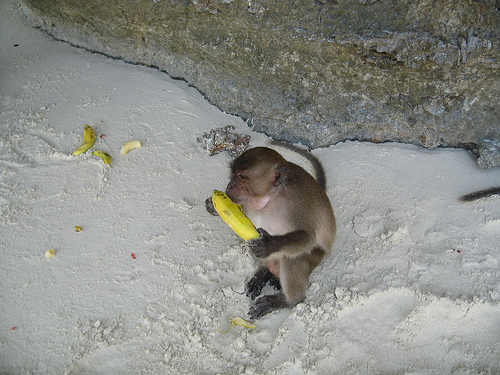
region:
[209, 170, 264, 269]
The monkey is holding a banana.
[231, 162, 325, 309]
A monkey sitting in the snow.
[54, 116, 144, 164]
Banana peel on the ground.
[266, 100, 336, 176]
The monkey has a long tail.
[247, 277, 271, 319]
Claws on the monkey.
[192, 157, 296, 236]
The monkey is eating a banana.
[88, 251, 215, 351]
Footprints on the snow.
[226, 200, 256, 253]
The banana is yellow.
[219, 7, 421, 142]
A big rock on side of monkey.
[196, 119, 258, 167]
A brown object on the snow.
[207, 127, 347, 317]
monkey holding banana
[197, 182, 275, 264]
a yellow banana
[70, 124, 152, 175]
a banana peel and a unpeeled banana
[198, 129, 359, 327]
monkey trying to eat banana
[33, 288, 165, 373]
a snow plain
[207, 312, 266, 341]
pieces of banana skin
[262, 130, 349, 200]
tail of a monkey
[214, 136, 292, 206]
head of a monkey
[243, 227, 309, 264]
arm of a monkey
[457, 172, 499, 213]
a monkey's tail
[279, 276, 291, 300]
part of a thigh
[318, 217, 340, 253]
part of a monkey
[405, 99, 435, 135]
oart of a wall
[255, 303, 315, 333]
aprt of a foot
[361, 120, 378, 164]
part of a rock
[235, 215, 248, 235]
part of a banana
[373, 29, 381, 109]
part of a rock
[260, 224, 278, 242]
part of a banana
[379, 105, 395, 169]
part of a stone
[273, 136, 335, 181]
The tail of the monkey.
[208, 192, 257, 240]
The banana in the monkey's hand.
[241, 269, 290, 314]
The feet of the monkey.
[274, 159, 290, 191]
The ear of the monkey.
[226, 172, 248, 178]
The eyes of the monkey.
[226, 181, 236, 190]
The nose of the monkey.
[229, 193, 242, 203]
The mouth of the monkey.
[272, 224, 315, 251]
The arm of the monkey.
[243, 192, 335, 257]
The body of the monkey.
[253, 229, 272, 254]
The hand of the monkey.